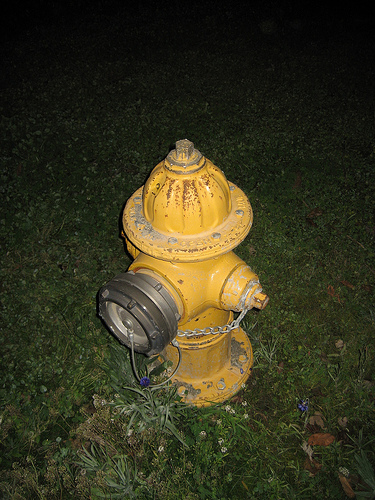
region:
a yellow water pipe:
[100, 162, 241, 391]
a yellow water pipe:
[147, 315, 241, 444]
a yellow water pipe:
[126, 274, 206, 458]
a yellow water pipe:
[163, 239, 249, 485]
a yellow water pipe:
[145, 273, 194, 399]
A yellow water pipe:
[84, 234, 212, 431]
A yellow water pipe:
[190, 332, 239, 451]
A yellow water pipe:
[113, 250, 237, 493]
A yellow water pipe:
[125, 242, 200, 398]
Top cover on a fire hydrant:
[110, 133, 257, 264]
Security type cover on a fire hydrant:
[87, 271, 180, 358]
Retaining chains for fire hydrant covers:
[183, 285, 247, 350]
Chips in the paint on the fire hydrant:
[222, 331, 253, 382]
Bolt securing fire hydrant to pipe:
[215, 376, 228, 393]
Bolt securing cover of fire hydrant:
[207, 229, 223, 240]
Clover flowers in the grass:
[197, 428, 231, 455]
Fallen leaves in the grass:
[298, 409, 338, 449]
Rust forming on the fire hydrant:
[178, 179, 197, 214]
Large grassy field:
[286, 109, 353, 366]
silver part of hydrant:
[83, 277, 185, 361]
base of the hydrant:
[178, 340, 264, 410]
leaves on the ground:
[276, 389, 363, 488]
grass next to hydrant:
[269, 349, 315, 396]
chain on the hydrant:
[189, 314, 248, 343]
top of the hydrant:
[135, 120, 231, 177]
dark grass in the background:
[22, 129, 96, 194]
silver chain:
[192, 297, 249, 348]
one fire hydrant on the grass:
[79, 147, 300, 413]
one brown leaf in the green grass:
[294, 427, 341, 454]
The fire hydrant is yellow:
[106, 145, 278, 405]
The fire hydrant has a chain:
[163, 286, 277, 346]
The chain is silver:
[169, 302, 270, 353]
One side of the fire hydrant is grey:
[93, 272, 182, 380]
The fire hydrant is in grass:
[47, 74, 307, 429]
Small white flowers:
[179, 377, 260, 462]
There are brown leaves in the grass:
[288, 400, 361, 493]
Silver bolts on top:
[160, 232, 180, 249]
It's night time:
[45, 19, 313, 143]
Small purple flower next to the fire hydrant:
[127, 375, 165, 394]